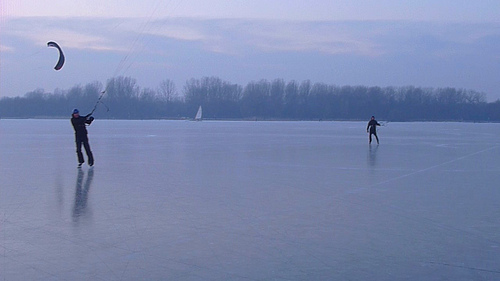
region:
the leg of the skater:
[74, 137, 84, 164]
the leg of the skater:
[84, 137, 96, 163]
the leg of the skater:
[368, 131, 374, 143]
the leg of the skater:
[371, 128, 381, 145]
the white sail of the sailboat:
[192, 104, 202, 118]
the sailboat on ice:
[192, 106, 202, 124]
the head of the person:
[72, 109, 79, 115]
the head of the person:
[370, 112, 376, 122]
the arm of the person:
[75, 109, 90, 124]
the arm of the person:
[364, 119, 373, 130]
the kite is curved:
[31, 21, 80, 86]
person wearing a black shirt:
[56, 95, 113, 147]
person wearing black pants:
[73, 132, 102, 164]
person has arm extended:
[363, 111, 390, 135]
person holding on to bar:
[63, 78, 117, 138]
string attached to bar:
[66, 50, 167, 144]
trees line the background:
[0, 60, 497, 134]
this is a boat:
[180, 93, 210, 129]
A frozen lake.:
[0, 115, 495, 279]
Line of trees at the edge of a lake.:
[3, 73, 498, 122]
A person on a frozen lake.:
[357, 111, 389, 147]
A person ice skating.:
[62, 105, 106, 172]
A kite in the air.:
[42, 35, 67, 75]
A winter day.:
[1, 3, 496, 278]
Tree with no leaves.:
[147, 78, 179, 118]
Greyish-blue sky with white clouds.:
[3, 1, 493, 81]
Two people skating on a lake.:
[57, 103, 392, 172]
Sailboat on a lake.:
[186, 105, 204, 122]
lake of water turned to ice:
[0, 115, 499, 280]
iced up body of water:
[0, 116, 499, 278]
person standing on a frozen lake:
[364, 112, 389, 144]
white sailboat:
[193, 105, 204, 122]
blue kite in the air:
[43, 37, 69, 74]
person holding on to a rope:
[68, 107, 101, 168]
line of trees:
[3, 72, 498, 134]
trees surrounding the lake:
[0, 70, 499, 128]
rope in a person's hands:
[82, 85, 114, 127]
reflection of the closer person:
[70, 164, 95, 226]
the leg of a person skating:
[75, 138, 81, 160]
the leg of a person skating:
[82, 138, 94, 163]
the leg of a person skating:
[367, 131, 372, 141]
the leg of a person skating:
[372, 131, 379, 141]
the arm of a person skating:
[71, 116, 89, 123]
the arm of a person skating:
[85, 115, 95, 123]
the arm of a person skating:
[362, 121, 372, 131]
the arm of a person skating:
[373, 122, 384, 129]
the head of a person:
[70, 107, 79, 118]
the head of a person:
[367, 113, 374, 123]